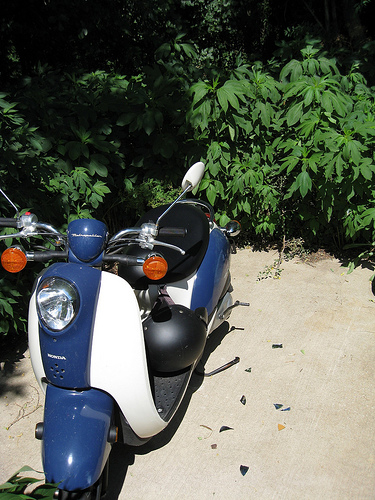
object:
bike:
[0, 160, 250, 497]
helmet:
[142, 305, 208, 375]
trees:
[265, 45, 356, 163]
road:
[258, 306, 340, 436]